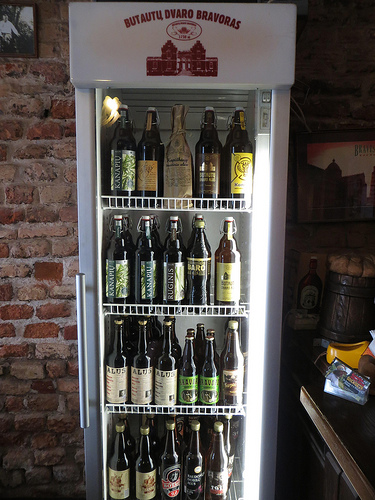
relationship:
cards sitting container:
[328, 358, 371, 390] [322, 378, 369, 402]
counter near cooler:
[281, 325, 374, 499] [68, 1, 297, 498]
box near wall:
[285, 260, 330, 336] [24, 345, 60, 401]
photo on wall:
[0, 1, 38, 58] [10, 69, 72, 379]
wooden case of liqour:
[277, 309, 367, 466] [293, 322, 331, 391]